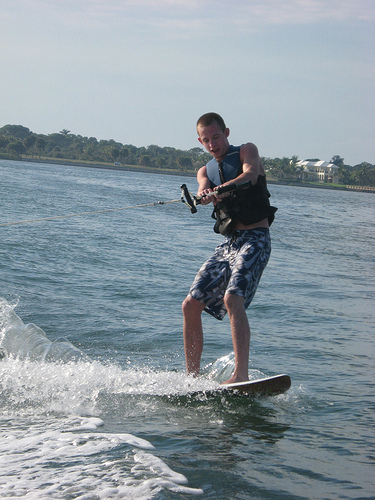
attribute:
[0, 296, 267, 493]
water — white 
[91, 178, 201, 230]
rope — black, grey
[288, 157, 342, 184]
house — Large 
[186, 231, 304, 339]
shorts — multi-print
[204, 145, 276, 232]
vest — blue, black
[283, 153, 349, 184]
building — white 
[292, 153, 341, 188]
house — white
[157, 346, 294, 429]
board — white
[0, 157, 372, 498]
water — dark blue, calm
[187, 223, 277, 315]
shorts — blue 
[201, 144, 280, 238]
vest — blue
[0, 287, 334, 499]
foam — white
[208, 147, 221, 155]
mouth — open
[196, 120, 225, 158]
face — rounded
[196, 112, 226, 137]
hair — short